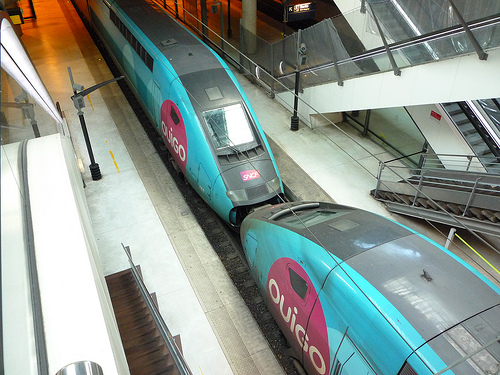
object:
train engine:
[239, 201, 499, 374]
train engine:
[152, 44, 286, 232]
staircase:
[104, 265, 185, 373]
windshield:
[202, 104, 260, 150]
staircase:
[370, 155, 499, 236]